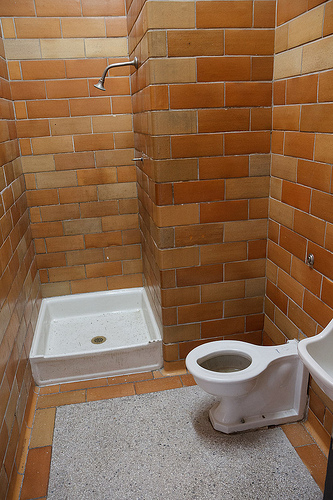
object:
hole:
[196, 349, 252, 372]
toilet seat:
[185, 336, 299, 398]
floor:
[45, 385, 324, 500]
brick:
[155, 158, 197, 183]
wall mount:
[93, 56, 139, 91]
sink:
[296, 317, 332, 401]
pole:
[321, 427, 333, 500]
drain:
[90, 335, 106, 346]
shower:
[0, 0, 163, 386]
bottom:
[29, 285, 164, 390]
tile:
[68, 411, 119, 443]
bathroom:
[0, 0, 332, 498]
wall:
[149, 0, 265, 369]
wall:
[125, 0, 160, 284]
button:
[306, 252, 314, 270]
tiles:
[166, 33, 256, 125]